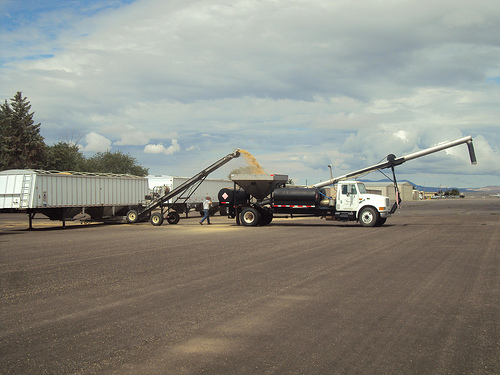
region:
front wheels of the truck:
[347, 202, 383, 233]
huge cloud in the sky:
[18, 12, 499, 172]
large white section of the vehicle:
[0, 160, 164, 232]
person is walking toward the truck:
[190, 190, 222, 229]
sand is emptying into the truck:
[223, 123, 295, 195]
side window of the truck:
[333, 181, 362, 206]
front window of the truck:
[351, 179, 372, 200]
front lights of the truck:
[371, 189, 401, 216]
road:
[7, 193, 495, 373]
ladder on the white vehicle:
[10, 166, 42, 207]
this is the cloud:
[118, 10, 263, 55]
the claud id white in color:
[360, 104, 406, 144]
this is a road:
[273, 239, 430, 354]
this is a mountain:
[404, 175, 496, 196]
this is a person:
[195, 192, 232, 247]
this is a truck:
[221, 162, 401, 230]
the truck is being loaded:
[203, 151, 399, 237]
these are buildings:
[377, 177, 444, 208]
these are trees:
[0, 96, 138, 171]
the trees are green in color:
[0, 112, 132, 174]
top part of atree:
[18, 92, 20, 104]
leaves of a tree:
[30, 135, 47, 156]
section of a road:
[354, 305, 410, 374]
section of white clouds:
[218, 42, 279, 89]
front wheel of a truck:
[366, 214, 373, 224]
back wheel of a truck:
[245, 212, 252, 223]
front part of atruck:
[376, 197, 390, 212]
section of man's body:
[206, 202, 209, 219]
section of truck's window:
[347, 187, 353, 193]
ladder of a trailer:
[22, 181, 29, 203]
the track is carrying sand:
[236, 151, 444, 272]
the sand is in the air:
[229, 138, 270, 176]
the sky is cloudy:
[192, 67, 470, 147]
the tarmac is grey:
[127, 237, 441, 368]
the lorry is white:
[33, 175, 155, 208]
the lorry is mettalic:
[23, 171, 162, 223]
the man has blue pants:
[193, 200, 216, 232]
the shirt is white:
[202, 197, 217, 212]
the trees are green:
[31, 140, 137, 170]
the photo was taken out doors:
[0, 60, 499, 362]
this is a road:
[153, 265, 333, 372]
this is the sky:
[136, 1, 431, 105]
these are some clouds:
[72, 31, 152, 105]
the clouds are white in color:
[123, 44, 218, 126]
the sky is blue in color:
[2, 0, 26, 20]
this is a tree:
[1, 98, 47, 168]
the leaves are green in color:
[9, 124, 33, 151]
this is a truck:
[237, 171, 392, 227]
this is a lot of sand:
[238, 150, 262, 177]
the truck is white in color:
[361, 195, 381, 201]